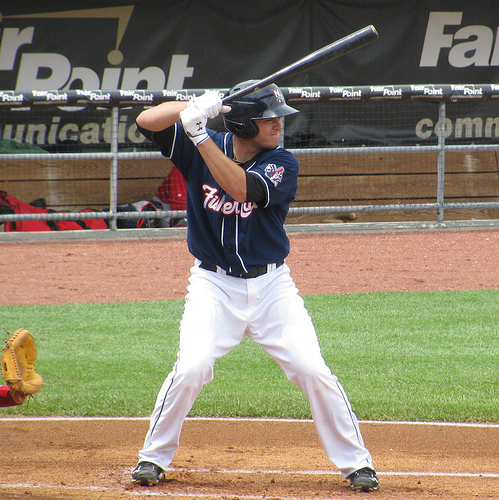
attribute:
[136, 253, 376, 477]
pants — white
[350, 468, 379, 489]
shoes — black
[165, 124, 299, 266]
jersey — blue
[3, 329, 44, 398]
mitt — brown, gold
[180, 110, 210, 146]
gloves — white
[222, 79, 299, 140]
helmet — black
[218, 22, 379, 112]
bat — black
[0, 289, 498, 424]
area — green, grassy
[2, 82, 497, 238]
fence — padded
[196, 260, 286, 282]
belt — black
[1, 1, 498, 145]
sign — blue, white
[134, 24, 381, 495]
man — playing, at bat